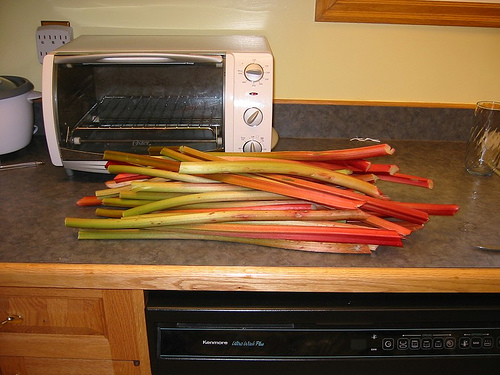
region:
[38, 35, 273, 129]
this is an oven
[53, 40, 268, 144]
the oven is closed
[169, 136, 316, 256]
these are the stalks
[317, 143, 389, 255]
the stalks are red in color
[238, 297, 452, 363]
the cooker is black in color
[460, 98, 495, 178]
this is a glass of water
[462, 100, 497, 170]
the glass is empty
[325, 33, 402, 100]
this is the wall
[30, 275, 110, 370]
the drawer is wooden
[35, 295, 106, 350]
the drawer is brown in color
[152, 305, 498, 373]
The dishwasher is black.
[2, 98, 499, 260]
Vegetables are lying on the counter.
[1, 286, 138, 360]
The drawer is wood.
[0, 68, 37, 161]
A small white crock pot.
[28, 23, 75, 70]
A plug is plugged into the wall.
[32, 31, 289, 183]
Convection oven has 3 knobs.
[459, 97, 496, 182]
The clear glass is empty.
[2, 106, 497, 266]
Counter has brown marbled top.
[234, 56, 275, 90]
Knob is set to heat.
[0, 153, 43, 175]
A black ink pen.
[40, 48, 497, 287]
sticks on a table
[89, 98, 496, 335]
green orange red sticks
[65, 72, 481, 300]
sticks in the kitchen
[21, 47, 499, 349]
sticks on a kitchen counter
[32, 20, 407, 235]
a toaster oven on the counter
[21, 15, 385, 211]
a toaster oven in the kitchen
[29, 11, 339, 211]
a toaster oven on a kitchen counter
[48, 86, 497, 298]
vegetables on the counter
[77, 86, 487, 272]
vegetable sticks on the counter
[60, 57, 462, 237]
a counter with vegetable sticks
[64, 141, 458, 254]
Red and green rhubarb on a counter top.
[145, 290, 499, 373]
A black Kenmore dishwasher under the counter.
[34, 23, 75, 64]
A six plug outlet on the wall.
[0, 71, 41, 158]
A white crock pot with clear lid.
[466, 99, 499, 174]
An upside down clear glass on the counter.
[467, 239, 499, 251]
A spoon on the counter.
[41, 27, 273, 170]
A white toaster oven sitting on the counter.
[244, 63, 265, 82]
Top silver knob on the right side of a toaster oven.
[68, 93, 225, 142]
Silver metal rack inside a toaster oven.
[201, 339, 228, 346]
The white word Kenmore on a black dishwasher.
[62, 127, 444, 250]
food on the table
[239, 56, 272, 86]
knob of the object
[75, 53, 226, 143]
oven in the photo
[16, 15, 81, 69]
outlet on the wall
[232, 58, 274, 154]
three knobs on the object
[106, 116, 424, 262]
many colorful items stacked on top of each other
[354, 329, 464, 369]
buttons on dishwasher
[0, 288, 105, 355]
brown part of counter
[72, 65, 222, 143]
empty oven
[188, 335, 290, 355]
words on the dishwasher